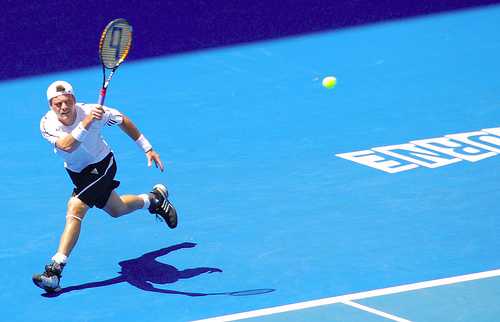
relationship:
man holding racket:
[32, 81, 178, 294] [98, 17, 133, 107]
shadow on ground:
[44, 241, 278, 307] [223, 199, 251, 216]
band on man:
[137, 133, 153, 156] [32, 81, 178, 294]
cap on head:
[48, 78, 76, 101] [48, 79, 77, 121]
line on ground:
[346, 298, 411, 321] [223, 199, 251, 216]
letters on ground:
[334, 122, 499, 174] [223, 199, 251, 216]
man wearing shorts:
[32, 81, 178, 294] [67, 152, 122, 208]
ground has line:
[223, 199, 251, 216] [346, 298, 411, 321]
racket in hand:
[98, 17, 133, 107] [88, 107, 106, 126]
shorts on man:
[67, 152, 122, 208] [32, 81, 178, 294]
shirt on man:
[39, 103, 123, 173] [32, 81, 178, 294]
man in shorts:
[32, 81, 178, 294] [67, 152, 122, 208]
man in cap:
[32, 81, 178, 294] [48, 78, 76, 101]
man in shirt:
[32, 81, 178, 294] [39, 103, 123, 173]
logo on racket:
[109, 25, 124, 60] [98, 17, 133, 107]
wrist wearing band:
[137, 133, 153, 156] [132, 132, 152, 152]